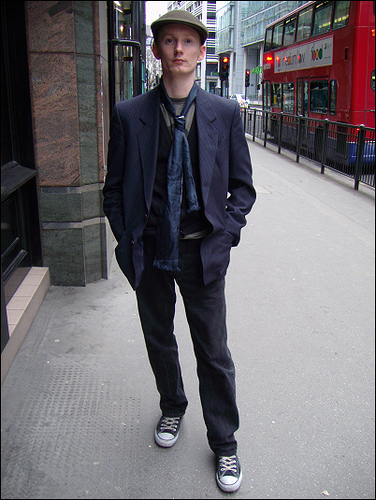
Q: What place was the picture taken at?
A: It was taken at the sidewalk.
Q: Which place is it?
A: It is a sidewalk.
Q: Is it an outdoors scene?
A: Yes, it is outdoors.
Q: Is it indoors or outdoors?
A: It is outdoors.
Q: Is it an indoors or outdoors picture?
A: It is outdoors.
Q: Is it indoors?
A: No, it is outdoors.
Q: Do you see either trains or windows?
A: Yes, there are windows.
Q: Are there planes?
A: No, there are no planes.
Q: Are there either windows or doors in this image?
A: Yes, there are windows.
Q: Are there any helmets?
A: No, there are no helmets.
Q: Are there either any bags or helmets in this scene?
A: No, there are no helmets or bags.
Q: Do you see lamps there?
A: No, there are no lamps.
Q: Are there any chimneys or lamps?
A: No, there are no lamps or chimneys.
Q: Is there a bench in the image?
A: No, there are no benches.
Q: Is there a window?
A: Yes, there are windows.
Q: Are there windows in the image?
A: Yes, there are windows.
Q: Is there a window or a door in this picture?
A: Yes, there are windows.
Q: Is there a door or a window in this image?
A: Yes, there are windows.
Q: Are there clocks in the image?
A: No, there are no clocks.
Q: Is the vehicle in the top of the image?
A: Yes, the vehicle is in the top of the image.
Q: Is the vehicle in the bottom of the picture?
A: No, the vehicle is in the top of the image.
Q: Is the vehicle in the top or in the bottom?
A: The vehicle is in the top of the image.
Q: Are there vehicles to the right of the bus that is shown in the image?
A: No, the vehicle is to the left of the bus.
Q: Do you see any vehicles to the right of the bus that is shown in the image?
A: No, the vehicle is to the left of the bus.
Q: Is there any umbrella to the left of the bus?
A: No, there is a vehicle to the left of the bus.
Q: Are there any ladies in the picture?
A: No, there are no ladies.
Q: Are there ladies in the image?
A: No, there are no ladies.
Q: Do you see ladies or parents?
A: No, there are no ladies or parents.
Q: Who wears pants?
A: The man wears pants.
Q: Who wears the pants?
A: The man wears pants.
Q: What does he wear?
A: The man wears pants.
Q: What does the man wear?
A: The man wears pants.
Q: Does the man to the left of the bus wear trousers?
A: Yes, the man wears trousers.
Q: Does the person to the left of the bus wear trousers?
A: Yes, the man wears trousers.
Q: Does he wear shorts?
A: No, the man wears trousers.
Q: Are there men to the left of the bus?
A: Yes, there is a man to the left of the bus.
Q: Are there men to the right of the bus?
A: No, the man is to the left of the bus.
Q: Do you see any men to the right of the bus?
A: No, the man is to the left of the bus.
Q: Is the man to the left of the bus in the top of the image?
A: Yes, the man is to the left of the bus.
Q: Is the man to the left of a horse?
A: No, the man is to the left of the bus.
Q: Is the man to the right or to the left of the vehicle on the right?
A: The man is to the left of the bus.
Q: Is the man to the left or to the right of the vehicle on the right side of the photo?
A: The man is to the left of the bus.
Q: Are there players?
A: No, there are no players.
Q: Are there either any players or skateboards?
A: No, there are no players or skateboards.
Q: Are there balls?
A: No, there are no balls.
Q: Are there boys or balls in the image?
A: No, there are no balls or boys.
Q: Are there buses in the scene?
A: Yes, there is a bus.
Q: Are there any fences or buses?
A: Yes, there is a bus.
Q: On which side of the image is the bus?
A: The bus is on the right of the image.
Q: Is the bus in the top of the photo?
A: Yes, the bus is in the top of the image.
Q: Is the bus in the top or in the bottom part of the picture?
A: The bus is in the top of the image.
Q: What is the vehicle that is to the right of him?
A: The vehicle is a bus.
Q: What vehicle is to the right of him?
A: The vehicle is a bus.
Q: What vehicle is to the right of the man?
A: The vehicle is a bus.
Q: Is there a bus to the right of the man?
A: Yes, there is a bus to the right of the man.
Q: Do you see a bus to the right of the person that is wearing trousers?
A: Yes, there is a bus to the right of the man.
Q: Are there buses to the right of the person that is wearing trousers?
A: Yes, there is a bus to the right of the man.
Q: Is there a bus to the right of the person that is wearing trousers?
A: Yes, there is a bus to the right of the man.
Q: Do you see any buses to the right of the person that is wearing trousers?
A: Yes, there is a bus to the right of the man.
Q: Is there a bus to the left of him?
A: No, the bus is to the right of the man.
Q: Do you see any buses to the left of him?
A: No, the bus is to the right of the man.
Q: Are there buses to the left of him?
A: No, the bus is to the right of the man.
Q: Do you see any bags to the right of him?
A: No, there is a bus to the right of the man.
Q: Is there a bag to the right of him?
A: No, there is a bus to the right of the man.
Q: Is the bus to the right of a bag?
A: No, the bus is to the right of a man.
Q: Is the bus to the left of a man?
A: No, the bus is to the right of a man.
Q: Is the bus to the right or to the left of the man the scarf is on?
A: The bus is to the right of the man.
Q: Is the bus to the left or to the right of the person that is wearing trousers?
A: The bus is to the right of the man.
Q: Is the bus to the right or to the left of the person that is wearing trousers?
A: The bus is to the right of the man.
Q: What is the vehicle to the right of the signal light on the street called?
A: The vehicle is a bus.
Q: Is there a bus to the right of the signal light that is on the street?
A: Yes, there is a bus to the right of the traffic light.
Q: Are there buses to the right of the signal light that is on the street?
A: Yes, there is a bus to the right of the traffic light.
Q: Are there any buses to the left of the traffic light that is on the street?
A: No, the bus is to the right of the traffic signal.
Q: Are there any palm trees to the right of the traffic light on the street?
A: No, there is a bus to the right of the traffic signal.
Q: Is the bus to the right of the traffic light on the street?
A: Yes, the bus is to the right of the traffic light.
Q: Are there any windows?
A: Yes, there is a window.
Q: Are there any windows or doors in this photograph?
A: Yes, there is a window.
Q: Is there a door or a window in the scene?
A: Yes, there is a window.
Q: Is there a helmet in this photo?
A: No, there are no helmets.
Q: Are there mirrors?
A: No, there are no mirrors.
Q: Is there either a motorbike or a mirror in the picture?
A: No, there are no mirrors or motorcycles.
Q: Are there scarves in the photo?
A: Yes, there is a scarf.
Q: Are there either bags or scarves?
A: Yes, there is a scarf.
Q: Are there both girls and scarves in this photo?
A: No, there is a scarf but no girls.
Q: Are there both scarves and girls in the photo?
A: No, there is a scarf but no girls.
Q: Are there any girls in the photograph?
A: No, there are no girls.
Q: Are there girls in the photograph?
A: No, there are no girls.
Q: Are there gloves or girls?
A: No, there are no girls or gloves.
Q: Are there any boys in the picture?
A: No, there are no boys.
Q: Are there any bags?
A: No, there are no bags.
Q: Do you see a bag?
A: No, there are no bags.